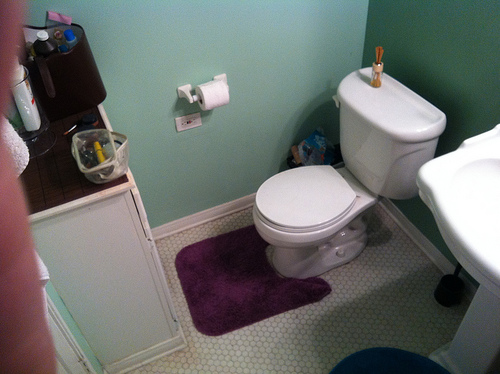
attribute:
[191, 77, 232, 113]
toilet paper — white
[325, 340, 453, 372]
mat — blue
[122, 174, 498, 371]
floor — white, tiled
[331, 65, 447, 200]
tank — white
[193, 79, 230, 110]
paper roll — white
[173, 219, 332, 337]
mat — purple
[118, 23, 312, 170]
wall — mint green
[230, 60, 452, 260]
toilet — white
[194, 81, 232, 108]
napkin roll — white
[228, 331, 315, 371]
tile — small, honeycomb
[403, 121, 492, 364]
sink — white, ceramic, pedestal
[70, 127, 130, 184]
bag — makeup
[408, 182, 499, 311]
sink — white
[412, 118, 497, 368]
sink — porcelain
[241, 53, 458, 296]
toilet — white